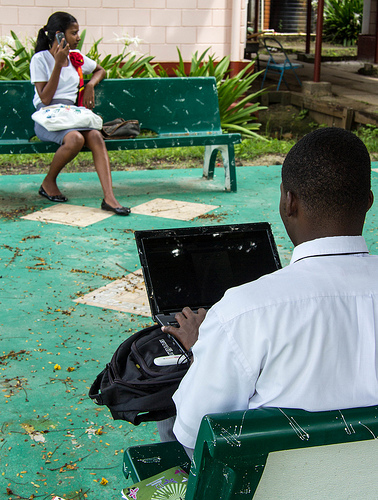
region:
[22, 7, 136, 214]
Woman on the phone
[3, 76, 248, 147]
Bench with woman on it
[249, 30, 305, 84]
Blue chair in background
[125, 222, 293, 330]
Laptop on man's lap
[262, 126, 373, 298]
Back of man's head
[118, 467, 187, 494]
Book next to man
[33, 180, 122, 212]
Woman's black shoes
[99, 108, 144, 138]
Bag next to woman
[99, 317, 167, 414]
Backpack with computer on top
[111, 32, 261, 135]
Bushes behind bench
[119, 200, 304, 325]
Black laptop being used by a man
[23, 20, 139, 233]
Woman sitting on a bench.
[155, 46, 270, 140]
Green bush behind a bench.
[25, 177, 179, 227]
Black shoes on a woman.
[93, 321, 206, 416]
Man with a black backpack.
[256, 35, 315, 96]
Turquoise chair in the background.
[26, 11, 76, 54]
Woman with ponytail.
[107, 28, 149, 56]
White flower on the bush.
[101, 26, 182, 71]
White petals on flower.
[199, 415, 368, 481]
Green bench man is sitting on.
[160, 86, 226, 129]
holes in green bench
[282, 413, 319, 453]
white scratches on dark green bench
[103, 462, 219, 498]
large green book cover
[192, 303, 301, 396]
seam in man's white shirt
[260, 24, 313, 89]
blue chair on the porch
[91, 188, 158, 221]
black flat shoes on girl's feet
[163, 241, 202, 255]
small spot on laptop screen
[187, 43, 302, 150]
green flowers behind the bench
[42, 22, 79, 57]
girl talking on her cell phone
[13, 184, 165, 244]
white square tile on ground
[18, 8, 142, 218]
a woman talking on her cell phone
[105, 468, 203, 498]
a textbook laying on a bench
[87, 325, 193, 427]
a black backpack on a lap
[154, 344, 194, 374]
a white jump drive in a laptop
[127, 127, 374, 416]
a man typing on his computer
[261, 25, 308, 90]
a blue folding chair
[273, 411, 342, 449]
white scratches on a bench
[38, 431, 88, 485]
debris on the ground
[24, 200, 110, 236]
white tile on a green pathway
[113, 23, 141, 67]
a white flower growing on a plant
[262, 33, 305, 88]
Blue metal fold up chair in the background.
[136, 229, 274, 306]
Laptop screen on the lap of the man.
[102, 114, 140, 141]
The girl's brown purse that is placed next to her on the bench.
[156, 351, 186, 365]
White USB stick on inserted on the side of the man's laptop.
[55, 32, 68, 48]
Cell phone in the girl's hand.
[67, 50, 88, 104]
Red rose ribbon pinned to the girl's shirt.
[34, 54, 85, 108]
White shirt worn by the girl sitting on the bench.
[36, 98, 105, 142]
Gray skirt worn by the girl sitting on the bench.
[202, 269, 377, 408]
White dress shirt worn by the man sitting on the bench.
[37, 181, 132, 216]
Black flat shoes worn by the girl sitting on the bench.